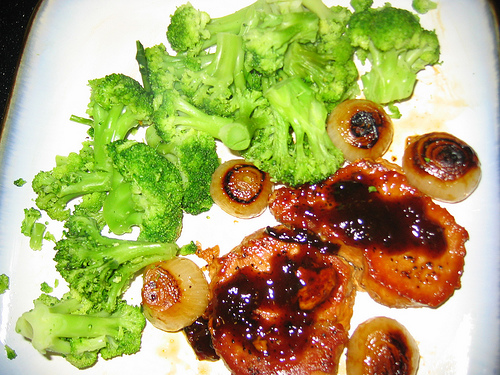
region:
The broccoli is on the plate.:
[38, 16, 395, 306]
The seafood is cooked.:
[150, 102, 460, 371]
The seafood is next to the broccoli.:
[0, 43, 489, 370]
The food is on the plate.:
[15, 2, 482, 371]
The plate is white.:
[4, 6, 494, 364]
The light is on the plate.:
[4, 6, 494, 373]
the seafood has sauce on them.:
[8, 9, 477, 370]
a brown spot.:
[216, 159, 263, 216]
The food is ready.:
[9, 7, 464, 372]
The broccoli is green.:
[5, 1, 492, 369]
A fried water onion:
[145, 251, 202, 328]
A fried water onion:
[214, 165, 275, 228]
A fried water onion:
[350, 307, 424, 372]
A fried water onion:
[324, 88, 384, 148]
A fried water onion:
[414, 127, 487, 197]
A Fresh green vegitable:
[58, 217, 159, 297]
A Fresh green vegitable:
[124, 151, 183, 237]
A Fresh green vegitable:
[84, 54, 133, 148]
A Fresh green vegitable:
[344, 9, 455, 131]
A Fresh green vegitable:
[262, 72, 332, 187]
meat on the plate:
[267, 166, 444, 303]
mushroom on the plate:
[126, 249, 210, 344]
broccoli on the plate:
[29, 270, 133, 360]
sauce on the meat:
[232, 283, 304, 345]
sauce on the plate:
[378, 80, 475, 130]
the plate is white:
[25, 38, 132, 137]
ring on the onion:
[225, 161, 263, 206]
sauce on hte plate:
[149, 333, 206, 372]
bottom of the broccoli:
[25, 316, 70, 342]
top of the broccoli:
[180, 142, 212, 211]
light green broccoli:
[17, 0, 437, 372]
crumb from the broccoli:
[8, 176, 27, 188]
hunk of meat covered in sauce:
[208, 231, 360, 373]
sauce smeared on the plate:
[157, 338, 180, 358]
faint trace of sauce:
[196, 365, 209, 373]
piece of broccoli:
[11, 288, 148, 363]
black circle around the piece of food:
[211, 155, 270, 216]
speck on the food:
[401, 253, 414, 262]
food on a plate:
[1, 0, 498, 373]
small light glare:
[360, 353, 372, 365]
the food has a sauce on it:
[208, 122, 478, 371]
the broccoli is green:
[55, 166, 203, 371]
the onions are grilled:
[128, 267, 265, 364]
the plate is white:
[18, 223, 358, 373]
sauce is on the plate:
[167, 285, 222, 348]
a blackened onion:
[329, 99, 464, 203]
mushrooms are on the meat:
[254, 242, 341, 295]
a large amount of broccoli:
[45, 12, 398, 277]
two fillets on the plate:
[199, 192, 389, 371]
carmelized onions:
[348, 325, 428, 346]